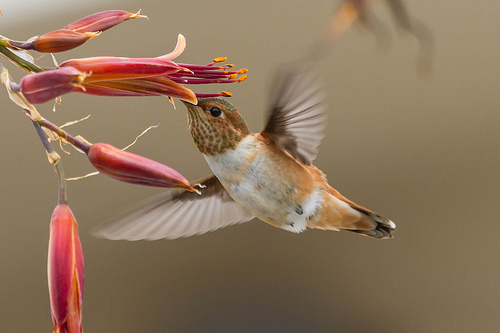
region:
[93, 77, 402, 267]
hummingbird hovering in the air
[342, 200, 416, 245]
tail feathers of bird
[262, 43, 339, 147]
bird wing in motion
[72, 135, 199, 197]
closed flower on stem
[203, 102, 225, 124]
black hummingbird eye with reflection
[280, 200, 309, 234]
feet tucked close to body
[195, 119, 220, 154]
spots on bird chin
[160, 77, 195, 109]
bird beak inside flower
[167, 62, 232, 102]
nectar of flower over bird head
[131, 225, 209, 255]
white tips of wing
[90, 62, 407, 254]
Humming bird flying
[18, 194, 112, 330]
Red flower petals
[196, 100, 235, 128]
Eye of a humming bird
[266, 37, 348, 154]
Flapping wing of a humming bird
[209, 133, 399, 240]
Brown and white feathers of a humming bird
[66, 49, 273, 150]
Humming bird searching in a flower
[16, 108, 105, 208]
Stem of flowers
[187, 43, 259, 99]
Yellow pollen of flower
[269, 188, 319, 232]
Feet of a humming bird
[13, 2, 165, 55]
Two pink flowers ready to bloom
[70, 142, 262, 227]
flower is red and orange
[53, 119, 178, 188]
flower is red and orange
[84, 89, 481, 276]
bird is white and brown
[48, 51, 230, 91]
this a flower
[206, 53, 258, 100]
these are yellow flower top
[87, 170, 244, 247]
this is the wings of a bird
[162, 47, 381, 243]
the bird is fying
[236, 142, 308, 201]
this is the birds fur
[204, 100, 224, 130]
this is the eye of a bird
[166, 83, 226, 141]
the bird is drinking nectar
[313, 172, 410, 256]
this is the birds tail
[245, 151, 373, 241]
the birds fur is brown in color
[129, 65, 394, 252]
the bird is small in size